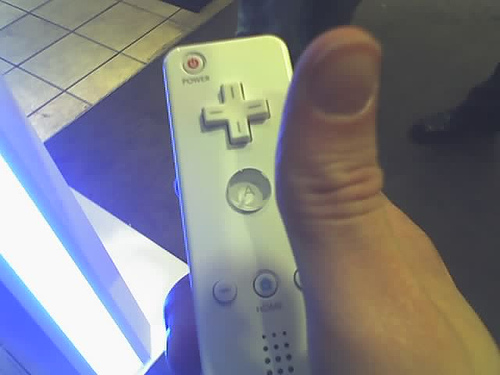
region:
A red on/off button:
[181, 56, 204, 80]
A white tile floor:
[11, 50, 82, 120]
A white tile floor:
[47, 16, 129, 88]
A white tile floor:
[97, 4, 191, 41]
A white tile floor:
[4, 2, 71, 62]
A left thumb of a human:
[290, 25, 425, 278]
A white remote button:
[197, 276, 251, 304]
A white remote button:
[245, 270, 279, 296]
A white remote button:
[224, 166, 281, 209]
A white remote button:
[208, 75, 268, 159]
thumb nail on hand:
[310, 38, 378, 122]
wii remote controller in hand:
[165, 34, 314, 371]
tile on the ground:
[2, 1, 138, 72]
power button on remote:
[184, 55, 207, 74]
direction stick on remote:
[202, 77, 272, 145]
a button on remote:
[227, 154, 273, 218]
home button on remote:
[251, 262, 278, 305]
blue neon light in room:
[6, 164, 151, 364]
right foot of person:
[407, 105, 472, 149]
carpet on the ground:
[76, 115, 167, 180]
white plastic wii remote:
[159, 33, 327, 373]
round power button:
[183, 53, 203, 72]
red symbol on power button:
[188, 54, 200, 68]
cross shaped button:
[201, 79, 272, 143]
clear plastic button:
[226, 167, 276, 206]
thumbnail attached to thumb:
[308, 38, 377, 115]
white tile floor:
[0, 0, 233, 144]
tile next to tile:
[16, 32, 117, 91]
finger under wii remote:
[163, 270, 201, 371]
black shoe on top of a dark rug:
[406, 108, 459, 141]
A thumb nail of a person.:
[304, 31, 378, 117]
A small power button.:
[187, 53, 199, 71]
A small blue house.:
[256, 272, 279, 296]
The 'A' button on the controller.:
[223, 167, 272, 212]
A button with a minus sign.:
[210, 278, 239, 305]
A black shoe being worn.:
[408, 91, 470, 159]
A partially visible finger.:
[160, 272, 204, 364]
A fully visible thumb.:
[270, 25, 438, 300]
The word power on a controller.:
[174, 73, 221, 85]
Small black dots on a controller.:
[258, 329, 300, 374]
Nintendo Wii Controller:
[148, 28, 322, 372]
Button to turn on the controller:
[155, 50, 217, 78]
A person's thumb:
[251, 31, 423, 356]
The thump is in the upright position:
[278, 28, 414, 373]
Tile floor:
[10, 6, 150, 87]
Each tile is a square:
[15, 8, 145, 99]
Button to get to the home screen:
[248, 262, 283, 313]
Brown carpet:
[68, 113, 166, 201]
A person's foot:
[401, 78, 486, 141]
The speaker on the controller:
[250, 317, 297, 374]